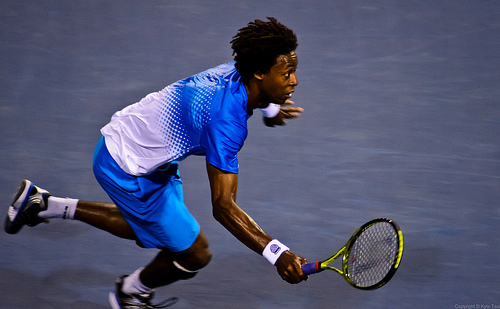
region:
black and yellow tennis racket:
[280, 209, 409, 295]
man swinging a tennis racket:
[1, 10, 451, 306]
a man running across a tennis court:
[1, 0, 425, 306]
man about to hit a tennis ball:
[1, 10, 440, 306]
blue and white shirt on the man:
[96, 62, 266, 193]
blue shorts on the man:
[88, 140, 207, 266]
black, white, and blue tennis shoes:
[0, 176, 200, 307]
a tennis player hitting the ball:
[8, 18, 413, 305]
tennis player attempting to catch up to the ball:
[1, 18, 413, 305]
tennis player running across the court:
[1, 5, 418, 306]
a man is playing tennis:
[5, 15, 308, 307]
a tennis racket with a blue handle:
[299, 217, 404, 291]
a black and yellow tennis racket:
[303, 218, 403, 291]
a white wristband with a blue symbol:
[261, 238, 288, 261]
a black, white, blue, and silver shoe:
[4, 178, 48, 235]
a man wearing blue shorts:
[6, 16, 309, 307]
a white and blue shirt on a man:
[98, 60, 252, 172]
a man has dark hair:
[5, 16, 307, 306]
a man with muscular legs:
[6, 15, 308, 306]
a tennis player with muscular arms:
[6, 17, 306, 307]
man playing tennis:
[3, 6, 432, 306]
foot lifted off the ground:
[4, 161, 70, 250]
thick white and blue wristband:
[249, 231, 301, 272]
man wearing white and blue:
[2, 3, 337, 306]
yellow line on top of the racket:
[386, 218, 416, 279]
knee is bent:
[157, 217, 233, 285]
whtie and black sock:
[36, 192, 86, 229]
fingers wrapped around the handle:
[267, 240, 326, 290]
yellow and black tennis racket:
[282, 213, 468, 292]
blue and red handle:
[290, 248, 324, 285]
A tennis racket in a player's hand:
[277, 202, 414, 298]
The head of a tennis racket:
[336, 213, 412, 295]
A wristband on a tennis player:
[256, 222, 313, 288]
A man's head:
[223, 10, 308, 118]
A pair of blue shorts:
[81, 126, 211, 266]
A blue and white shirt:
[93, 47, 257, 180]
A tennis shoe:
[3, 172, 55, 247]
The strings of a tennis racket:
[350, 231, 397, 276]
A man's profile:
[279, 53, 302, 109]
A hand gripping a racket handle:
[273, 237, 329, 302]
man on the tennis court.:
[55, 25, 415, 285]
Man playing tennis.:
[67, 13, 436, 305]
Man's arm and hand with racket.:
[254, 165, 414, 283]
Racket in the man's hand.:
[275, 196, 404, 290]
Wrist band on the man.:
[250, 216, 314, 277]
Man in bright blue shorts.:
[56, 26, 334, 262]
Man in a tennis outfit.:
[91, 11, 370, 270]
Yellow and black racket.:
[275, 190, 432, 301]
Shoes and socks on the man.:
[14, 171, 79, 243]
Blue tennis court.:
[66, 10, 163, 82]